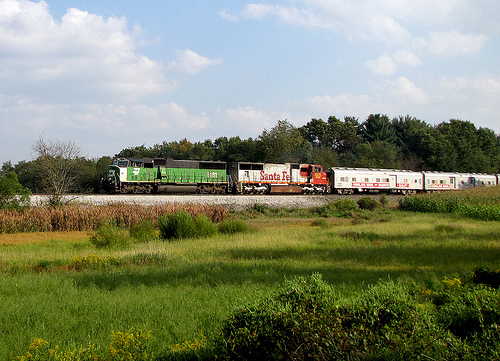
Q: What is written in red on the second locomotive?
A: Santa Fe.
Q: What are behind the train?
A: Trees.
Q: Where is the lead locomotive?
A: On the left.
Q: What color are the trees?
A: Green.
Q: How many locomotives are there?
A: Two.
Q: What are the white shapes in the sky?
A: Clouds.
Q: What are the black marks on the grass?
A: Shadows.